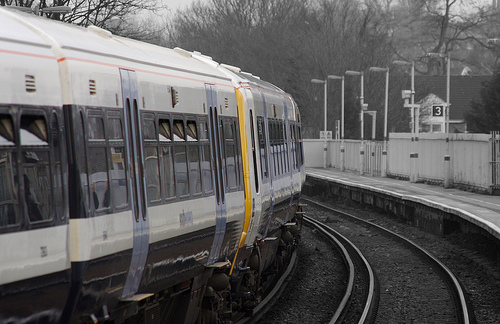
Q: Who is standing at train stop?
A: No people.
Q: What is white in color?
A: Passenger train.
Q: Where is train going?
A: Around a curve.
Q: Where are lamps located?
A: By white fence.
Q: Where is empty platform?
A: Right of train.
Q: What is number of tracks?
A: Two.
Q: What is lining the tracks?
A: Light posts.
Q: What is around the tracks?
A: A fence.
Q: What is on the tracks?
A: A train.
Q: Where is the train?
A: On the tracks.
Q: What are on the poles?
A: Lights.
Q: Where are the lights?
A: On the poles.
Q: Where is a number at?
A: The sign.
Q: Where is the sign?
A: On the pole.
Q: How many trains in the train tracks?
A: One.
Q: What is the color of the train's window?
A: Black.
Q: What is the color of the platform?
A: White.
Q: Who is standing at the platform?
A: No one.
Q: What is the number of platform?
A: Three.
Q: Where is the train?
A: In the train tracks.